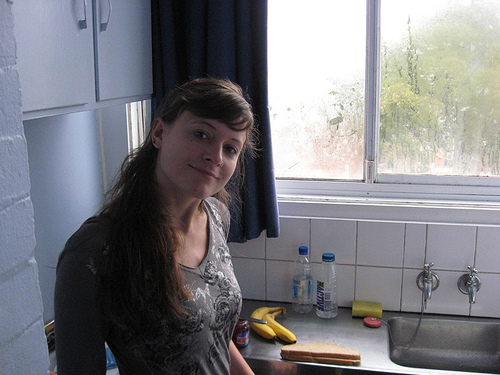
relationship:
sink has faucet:
[390, 316, 497, 371] [457, 263, 480, 305]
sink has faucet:
[390, 316, 497, 371] [413, 258, 443, 300]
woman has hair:
[54, 75, 256, 375] [128, 164, 173, 279]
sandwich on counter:
[274, 334, 368, 373] [234, 281, 497, 373]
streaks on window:
[394, 42, 461, 134] [377, 24, 497, 178]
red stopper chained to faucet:
[363, 316, 381, 327] [414, 253, 441, 303]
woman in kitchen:
[54, 75, 256, 375] [0, 4, 496, 369]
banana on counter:
[245, 299, 286, 344] [232, 296, 499, 373]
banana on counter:
[262, 305, 300, 343] [232, 296, 499, 373]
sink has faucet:
[385, 316, 497, 371] [415, 259, 439, 299]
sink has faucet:
[385, 316, 497, 371] [458, 262, 483, 307]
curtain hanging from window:
[149, 0, 281, 244] [266, 5, 498, 185]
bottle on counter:
[312, 253, 341, 323] [242, 297, 395, 370]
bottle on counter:
[290, 242, 315, 316] [242, 297, 395, 370]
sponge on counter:
[343, 301, 400, 325] [232, 296, 499, 373]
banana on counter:
[248, 300, 285, 340] [232, 296, 499, 373]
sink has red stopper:
[385, 316, 497, 371] [363, 316, 381, 327]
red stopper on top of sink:
[363, 316, 381, 327] [379, 312, 499, 372]